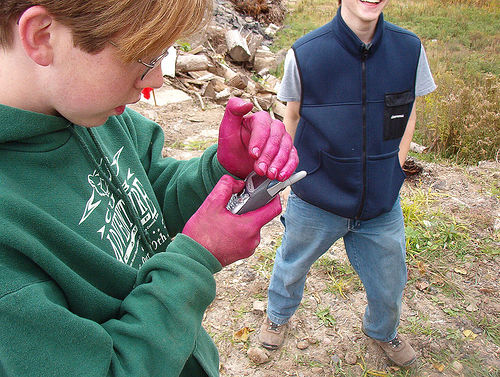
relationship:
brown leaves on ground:
[434, 284, 485, 342] [124, 0, 499, 376]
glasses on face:
[110, 37, 196, 85] [112, 40, 172, 93]